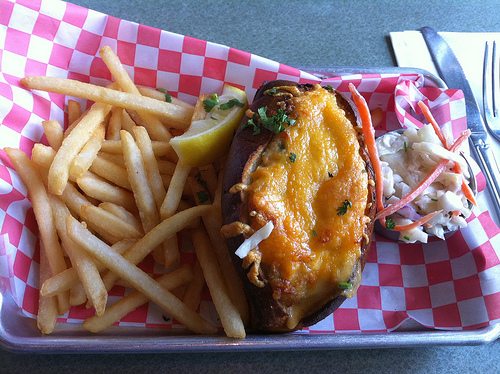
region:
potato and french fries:
[29, 19, 426, 368]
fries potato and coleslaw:
[57, 14, 490, 369]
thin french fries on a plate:
[42, 38, 204, 371]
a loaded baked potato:
[239, 62, 377, 357]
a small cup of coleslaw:
[369, 69, 496, 290]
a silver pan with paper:
[21, 25, 467, 372]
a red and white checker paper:
[11, 19, 498, 354]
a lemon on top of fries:
[54, 47, 446, 332]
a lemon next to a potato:
[157, 23, 412, 370]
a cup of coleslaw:
[304, 53, 495, 282]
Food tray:
[0, 68, 497, 349]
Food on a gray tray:
[2, 65, 496, 352]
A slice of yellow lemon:
[169, 78, 246, 160]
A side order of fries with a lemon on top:
[5, 42, 242, 338]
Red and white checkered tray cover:
[6, 0, 487, 327]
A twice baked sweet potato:
[216, 75, 381, 332]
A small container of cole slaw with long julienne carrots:
[370, 119, 476, 249]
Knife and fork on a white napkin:
[391, 27, 497, 202]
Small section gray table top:
[234, 0, 305, 44]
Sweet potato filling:
[263, 95, 364, 300]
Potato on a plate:
[252, 88, 377, 286]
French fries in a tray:
[33, 114, 195, 304]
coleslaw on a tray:
[381, 130, 471, 239]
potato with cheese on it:
[234, 127, 367, 307]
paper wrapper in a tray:
[371, 238, 486, 328]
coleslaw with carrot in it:
[390, 134, 487, 226]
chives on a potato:
[240, 93, 334, 248]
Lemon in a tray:
[158, 65, 243, 168]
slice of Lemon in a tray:
[163, 74, 279, 181]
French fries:
[50, 81, 156, 271]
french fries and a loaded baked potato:
[91, 57, 388, 347]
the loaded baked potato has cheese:
[234, 68, 356, 320]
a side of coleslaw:
[360, 79, 497, 264]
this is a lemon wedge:
[144, 52, 306, 241]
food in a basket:
[14, 26, 474, 345]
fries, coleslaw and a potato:
[40, 34, 495, 286]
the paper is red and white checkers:
[68, 16, 488, 308]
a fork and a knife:
[409, 36, 491, 112]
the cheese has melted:
[163, 50, 409, 370]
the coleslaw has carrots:
[361, 67, 461, 224]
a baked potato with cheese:
[222, 47, 399, 335]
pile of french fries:
[11, 26, 304, 366]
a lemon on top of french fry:
[12, 5, 286, 342]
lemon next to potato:
[169, 22, 447, 339]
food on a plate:
[17, 14, 497, 368]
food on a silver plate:
[25, 18, 497, 358]